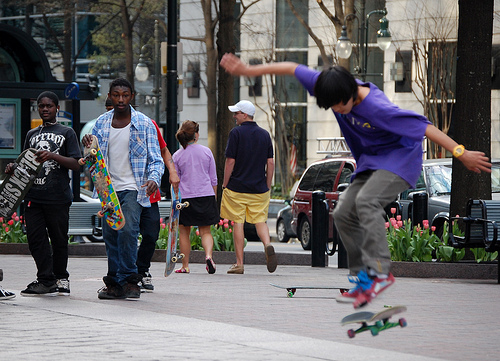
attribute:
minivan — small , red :
[288, 157, 360, 250]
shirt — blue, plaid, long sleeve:
[87, 103, 167, 209]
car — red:
[289, 156, 352, 250]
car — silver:
[396, 156, 451, 238]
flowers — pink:
[383, 206, 440, 260]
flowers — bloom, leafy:
[385, 202, 443, 264]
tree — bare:
[391, 0, 454, 159]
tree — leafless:
[386, 2, 456, 159]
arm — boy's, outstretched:
[392, 106, 462, 157]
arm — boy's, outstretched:
[248, 60, 312, 88]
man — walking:
[220, 100, 278, 275]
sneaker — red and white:
[354, 271, 395, 309]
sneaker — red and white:
[333, 277, 356, 302]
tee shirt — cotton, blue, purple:
[291, 63, 431, 187]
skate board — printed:
[79, 135, 129, 234]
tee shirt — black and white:
[22, 125, 81, 201]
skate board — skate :
[267, 282, 347, 295]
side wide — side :
[16, 257, 481, 357]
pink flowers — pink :
[387, 206, 441, 261]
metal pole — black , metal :
[312, 188, 327, 265]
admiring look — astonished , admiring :
[111, 91, 130, 106]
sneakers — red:
[350, 270, 391, 313]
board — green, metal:
[337, 304, 413, 345]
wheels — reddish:
[342, 316, 409, 339]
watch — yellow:
[448, 140, 466, 161]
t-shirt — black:
[4, 125, 71, 194]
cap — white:
[222, 94, 260, 119]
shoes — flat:
[173, 253, 222, 276]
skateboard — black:
[1, 134, 48, 235]